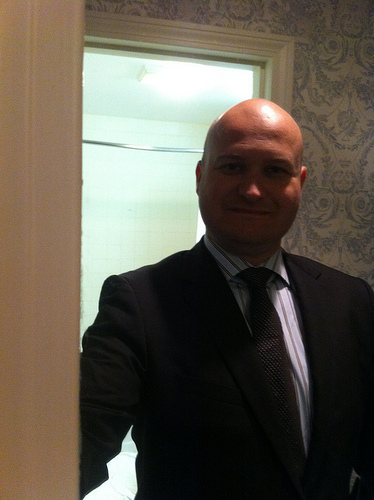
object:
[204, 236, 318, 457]
shirt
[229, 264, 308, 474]
tie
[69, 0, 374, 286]
wallpaper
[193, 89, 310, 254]
head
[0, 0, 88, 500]
door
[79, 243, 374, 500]
jacket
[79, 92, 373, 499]
man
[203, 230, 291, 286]
collar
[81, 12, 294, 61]
frame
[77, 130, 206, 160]
rod